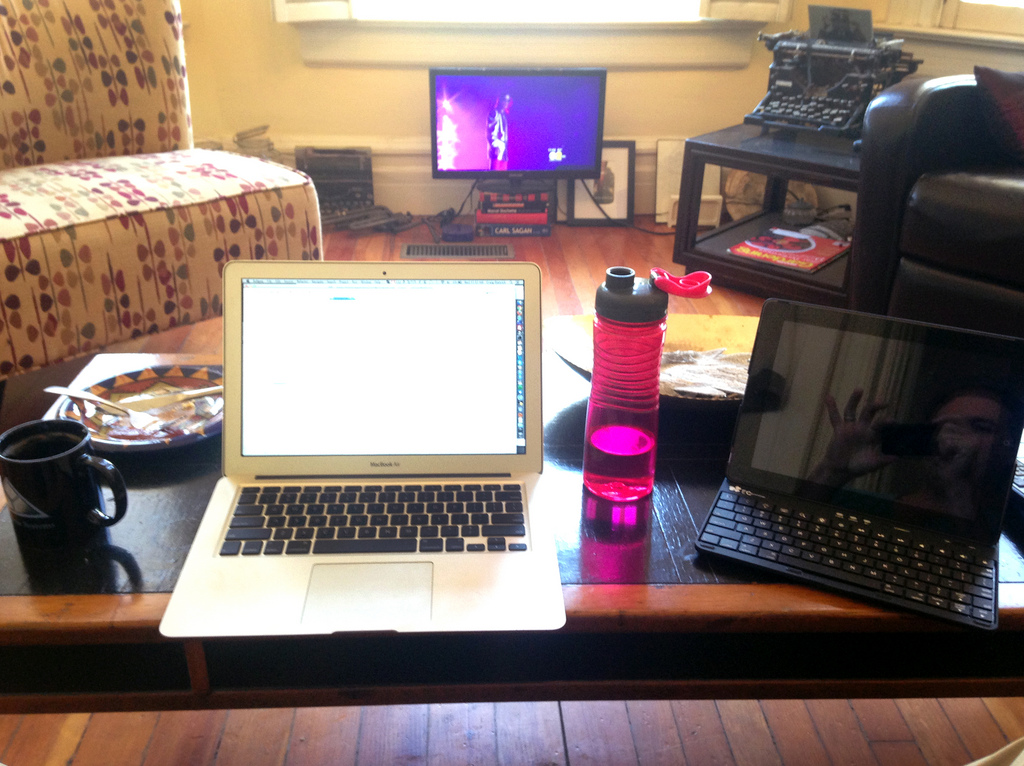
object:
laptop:
[159, 260, 567, 636]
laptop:
[693, 298, 1022, 633]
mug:
[0, 420, 128, 550]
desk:
[0, 354, 1024, 717]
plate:
[55, 365, 222, 452]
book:
[726, 226, 854, 274]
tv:
[429, 66, 609, 179]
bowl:
[555, 335, 787, 414]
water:
[581, 425, 655, 500]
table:
[671, 121, 899, 315]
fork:
[43, 385, 185, 437]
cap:
[649, 268, 714, 300]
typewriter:
[744, 5, 925, 153]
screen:
[748, 319, 1017, 524]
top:
[595, 266, 713, 323]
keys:
[214, 484, 524, 556]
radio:
[295, 146, 374, 231]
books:
[476, 190, 556, 237]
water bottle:
[581, 265, 712, 542]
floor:
[2, 214, 1023, 766]